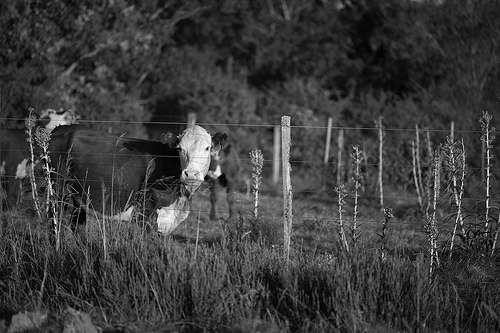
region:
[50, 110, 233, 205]
A cow in the photo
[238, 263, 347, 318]
Grass in the photo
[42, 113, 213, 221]
A white and black cow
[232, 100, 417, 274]
A fence in the photo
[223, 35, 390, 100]
Trees at the back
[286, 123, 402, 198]
Wire on the fence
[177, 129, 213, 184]
White head of a cow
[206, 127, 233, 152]
Black ear of a cow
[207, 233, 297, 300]
Tall grass in the field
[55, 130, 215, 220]
A cow in the field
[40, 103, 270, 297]
cow standing behind fence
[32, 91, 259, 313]
cow standing behind fence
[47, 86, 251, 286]
cow standing behind fence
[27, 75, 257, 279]
cow standing behind fence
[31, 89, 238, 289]
cow standing behind fence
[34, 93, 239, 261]
cow standing behind fence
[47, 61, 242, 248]
cow standing behind fence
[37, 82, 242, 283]
cow standing behind fence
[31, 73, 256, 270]
cow standing behind fence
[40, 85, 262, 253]
cow standing behind fence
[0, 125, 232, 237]
a cow standing behind a fence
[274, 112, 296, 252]
a wooden fence post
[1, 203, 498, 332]
tall grass near the fence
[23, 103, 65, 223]
plants coming out of the tall grass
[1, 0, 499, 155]
a line of trees behind the field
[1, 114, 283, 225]
metal wires on the fence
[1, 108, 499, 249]
a fence to keep the cow penned in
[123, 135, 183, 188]
a shadow on the cow's back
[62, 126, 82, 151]
a protruding hip bone of the cow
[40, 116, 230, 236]
a cow standing in a field of tall grass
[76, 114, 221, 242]
a cow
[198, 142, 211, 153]
the cows eye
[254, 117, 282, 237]
a wire fence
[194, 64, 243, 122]
the bushes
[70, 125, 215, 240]
a cow in the field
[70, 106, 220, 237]
the cow is standing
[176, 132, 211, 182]
cows face is white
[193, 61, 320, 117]
the bushes are big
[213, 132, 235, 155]
the cows ear is brown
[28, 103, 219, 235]
a fully grown adult cow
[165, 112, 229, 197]
the face of a brown cow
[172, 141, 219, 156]
the eyes a brown cow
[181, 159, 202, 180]
the nose a brown cow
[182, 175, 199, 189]
the mouth a brown cow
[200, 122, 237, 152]
the ear a brown cow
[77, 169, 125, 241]
the belly a brown cow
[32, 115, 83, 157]
the behind a brown cow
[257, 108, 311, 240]
a tall brown wooden post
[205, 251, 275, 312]
a bunch of dry grass